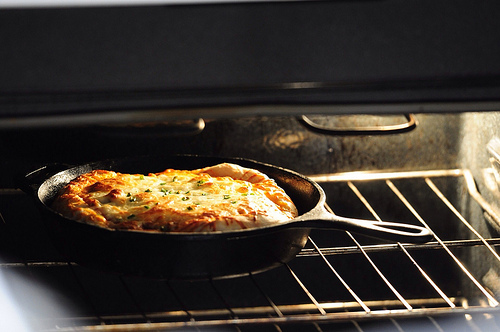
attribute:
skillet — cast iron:
[16, 139, 452, 268]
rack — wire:
[295, 177, 486, 322]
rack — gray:
[316, 162, 496, 292]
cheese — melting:
[53, 156, 358, 281]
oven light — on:
[316, 97, 496, 170]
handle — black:
[306, 206, 432, 241]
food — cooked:
[27, 143, 443, 276]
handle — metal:
[318, 210, 450, 255]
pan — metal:
[38, 211, 305, 276]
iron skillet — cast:
[34, 145, 432, 260]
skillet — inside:
[12, 117, 467, 288]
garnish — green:
[115, 175, 215, 227]